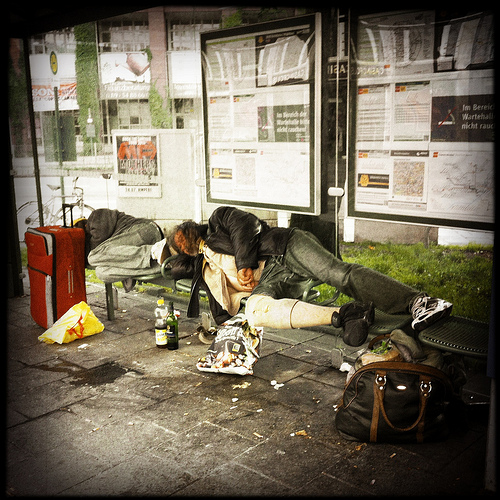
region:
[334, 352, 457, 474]
black bag on sidewalk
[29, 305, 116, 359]
yellow bag on sidewalk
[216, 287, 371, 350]
fake leg on man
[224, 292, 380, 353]
man with fake leg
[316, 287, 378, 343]
black shoe on man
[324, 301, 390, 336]
man with black shoe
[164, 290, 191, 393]
green bottle on sidewalk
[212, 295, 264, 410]
black bag by man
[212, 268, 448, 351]
man laying on bench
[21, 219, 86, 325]
red bag on sidewalk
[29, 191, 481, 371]
Two people sleeping at a busstop.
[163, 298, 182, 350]
A tall green bottle.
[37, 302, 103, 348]
A yellow plastic bag.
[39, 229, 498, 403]
A long silver bench.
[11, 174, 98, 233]
A bicycle.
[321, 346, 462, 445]
A black bag with brown handles.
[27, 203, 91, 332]
A black, red, and white suitcase.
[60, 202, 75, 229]
A black suitcase handle.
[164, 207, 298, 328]
A black coat.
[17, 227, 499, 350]
The green grass.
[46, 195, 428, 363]
two men sleeping on benches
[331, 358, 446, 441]
black bag with brown trim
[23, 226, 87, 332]
red suitcase with gray and black trim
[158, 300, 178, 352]
green bottle on ground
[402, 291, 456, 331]
white and black shoe of man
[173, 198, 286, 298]
black jacket of man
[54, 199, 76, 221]
black handle of red suitcase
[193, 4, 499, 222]
two posters framed on wall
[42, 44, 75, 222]
street sign outside of shelter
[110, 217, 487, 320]
bushes behind glass shelter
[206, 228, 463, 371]
man wearing black jeans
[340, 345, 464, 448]
black bag on the ground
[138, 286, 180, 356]
bottles on the ground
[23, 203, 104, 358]
Red luggage near the man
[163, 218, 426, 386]
man laying on a bench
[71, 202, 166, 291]
Man sleep on a bench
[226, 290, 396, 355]
man with a posterity leg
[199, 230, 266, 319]
man with a white shirt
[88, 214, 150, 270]
man wearing gray pants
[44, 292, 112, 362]
yellow bag on the ground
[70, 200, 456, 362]
two men sleeping on benches outdoors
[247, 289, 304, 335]
tan bandage on knee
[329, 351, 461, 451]
dark brown bag with brown handles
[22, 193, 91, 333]
red suitcase with black handles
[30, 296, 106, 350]
yellow bag on ground next to red suitcase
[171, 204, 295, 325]
black long sleeve leather jacket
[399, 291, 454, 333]
black and white sneaker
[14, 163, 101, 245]
bicycle parked on sidewalk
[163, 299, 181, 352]
bottled beverage on ground next to bench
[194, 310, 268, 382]
black and white bag of chips on sidewalk